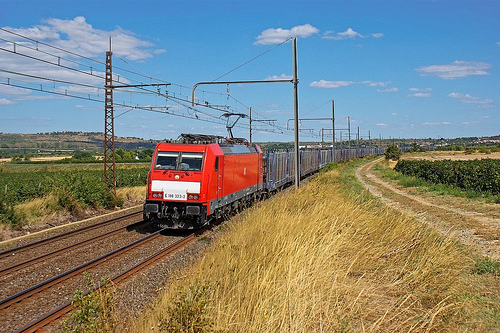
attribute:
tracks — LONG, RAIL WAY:
[17, 220, 137, 289]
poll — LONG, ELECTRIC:
[275, 20, 321, 192]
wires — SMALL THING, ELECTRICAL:
[46, 35, 256, 135]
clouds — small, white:
[237, 16, 395, 66]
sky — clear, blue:
[2, 2, 483, 142]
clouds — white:
[6, 9, 165, 114]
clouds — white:
[4, 12, 166, 122]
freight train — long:
[144, 128, 389, 229]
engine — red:
[140, 130, 267, 230]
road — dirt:
[349, 156, 484, 265]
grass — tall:
[176, 182, 433, 329]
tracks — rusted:
[3, 229, 184, 331]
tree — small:
[376, 139, 406, 162]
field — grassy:
[2, 158, 161, 203]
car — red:
[137, 140, 267, 232]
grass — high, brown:
[201, 175, 433, 331]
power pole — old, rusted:
[96, 30, 120, 193]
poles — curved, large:
[186, 34, 305, 194]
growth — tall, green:
[394, 155, 484, 190]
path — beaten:
[352, 158, 484, 258]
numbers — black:
[165, 190, 188, 200]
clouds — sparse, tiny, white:
[304, 52, 484, 123]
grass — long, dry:
[150, 156, 495, 328]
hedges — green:
[395, 153, 498, 198]